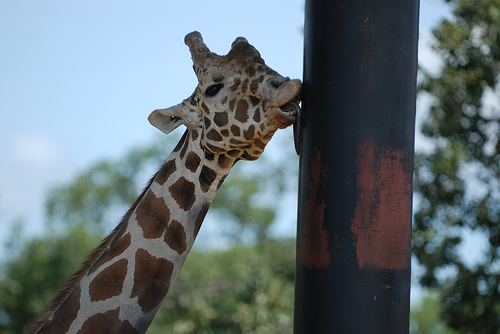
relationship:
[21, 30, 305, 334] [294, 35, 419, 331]
giraffe licking post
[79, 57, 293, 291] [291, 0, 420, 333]
giraffe licking black pole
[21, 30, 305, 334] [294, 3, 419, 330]
giraffe licking pole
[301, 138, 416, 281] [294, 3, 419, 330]
spots on pole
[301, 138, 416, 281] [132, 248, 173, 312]
spots on brown spots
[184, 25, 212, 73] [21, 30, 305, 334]
horn on giraffe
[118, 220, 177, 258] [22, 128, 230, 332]
middle of giraffe's neck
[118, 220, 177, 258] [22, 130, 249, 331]
middle of giraffe's neck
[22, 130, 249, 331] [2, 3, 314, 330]
giraffe's neck of giraffe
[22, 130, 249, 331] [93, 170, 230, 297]
giraffe's neck of giraffe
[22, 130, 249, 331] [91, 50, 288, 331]
giraffe's neck of giraffe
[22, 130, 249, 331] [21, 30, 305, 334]
giraffe's neck of giraffe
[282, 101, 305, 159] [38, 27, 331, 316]
tongue of giraffe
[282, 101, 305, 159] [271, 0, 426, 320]
tongue on pole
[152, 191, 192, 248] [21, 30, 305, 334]
brown spot on giraffe